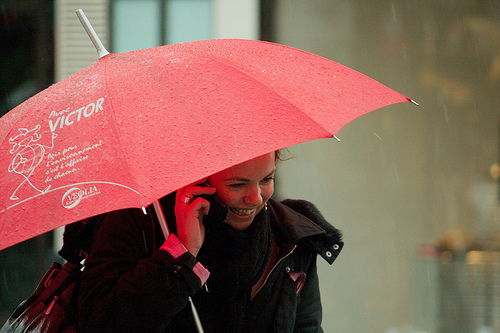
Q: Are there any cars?
A: No, there are no cars.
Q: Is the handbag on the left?
A: Yes, the handbag is on the left of the image.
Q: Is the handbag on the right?
A: No, the handbag is on the left of the image.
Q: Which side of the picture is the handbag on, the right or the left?
A: The handbag is on the left of the image.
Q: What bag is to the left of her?
A: The bag is a handbag.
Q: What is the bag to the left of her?
A: The bag is a handbag.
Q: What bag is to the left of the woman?
A: The bag is a handbag.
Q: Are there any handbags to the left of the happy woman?
A: Yes, there is a handbag to the left of the woman.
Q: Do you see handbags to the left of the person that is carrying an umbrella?
A: Yes, there is a handbag to the left of the woman.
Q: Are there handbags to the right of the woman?
A: No, the handbag is to the left of the woman.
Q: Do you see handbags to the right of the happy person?
A: No, the handbag is to the left of the woman.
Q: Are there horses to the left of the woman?
A: No, there is a handbag to the left of the woman.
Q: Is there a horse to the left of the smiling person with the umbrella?
A: No, there is a handbag to the left of the woman.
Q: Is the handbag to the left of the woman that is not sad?
A: Yes, the handbag is to the left of the woman.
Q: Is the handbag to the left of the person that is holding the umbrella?
A: Yes, the handbag is to the left of the woman.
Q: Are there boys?
A: No, there are no boys.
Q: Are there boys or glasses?
A: No, there are no boys or glasses.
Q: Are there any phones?
A: Yes, there is a phone.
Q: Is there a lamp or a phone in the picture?
A: Yes, there is a phone.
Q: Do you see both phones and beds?
A: No, there is a phone but no beds.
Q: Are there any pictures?
A: No, there are no pictures.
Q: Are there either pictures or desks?
A: No, there are no pictures or desks.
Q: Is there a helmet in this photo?
A: No, there are no helmets.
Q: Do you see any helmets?
A: No, there are no helmets.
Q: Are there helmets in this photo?
A: No, there are no helmets.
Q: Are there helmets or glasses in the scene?
A: No, there are no helmets or glasses.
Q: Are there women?
A: Yes, there is a woman.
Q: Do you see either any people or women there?
A: Yes, there is a woman.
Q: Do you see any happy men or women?
A: Yes, there is a happy woman.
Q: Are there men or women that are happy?
A: Yes, the woman is happy.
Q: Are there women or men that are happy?
A: Yes, the woman is happy.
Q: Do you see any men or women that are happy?
A: Yes, the woman is happy.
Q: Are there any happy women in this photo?
A: Yes, there is a happy woman.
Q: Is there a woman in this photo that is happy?
A: Yes, there is a woman that is happy.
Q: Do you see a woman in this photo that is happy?
A: Yes, there is a woman that is happy.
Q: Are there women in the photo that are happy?
A: Yes, there is a woman that is happy.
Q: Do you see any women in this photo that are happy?
A: Yes, there is a woman that is happy.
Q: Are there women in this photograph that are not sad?
A: Yes, there is a happy woman.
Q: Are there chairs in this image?
A: No, there are no chairs.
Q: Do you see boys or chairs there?
A: No, there are no chairs or boys.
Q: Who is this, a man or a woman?
A: This is a woman.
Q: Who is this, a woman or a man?
A: This is a woman.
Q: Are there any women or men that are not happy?
A: No, there is a woman but she is happy.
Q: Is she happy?
A: Yes, the woman is happy.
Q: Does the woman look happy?
A: Yes, the woman is happy.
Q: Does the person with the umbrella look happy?
A: Yes, the woman is happy.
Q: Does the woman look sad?
A: No, the woman is happy.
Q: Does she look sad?
A: No, the woman is happy.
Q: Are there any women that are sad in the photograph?
A: No, there is a woman but she is happy.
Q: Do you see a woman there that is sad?
A: No, there is a woman but she is happy.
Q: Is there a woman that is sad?
A: No, there is a woman but she is happy.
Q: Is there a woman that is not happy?
A: No, there is a woman but she is happy.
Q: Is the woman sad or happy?
A: The woman is happy.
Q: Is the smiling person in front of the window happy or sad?
A: The woman is happy.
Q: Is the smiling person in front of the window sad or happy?
A: The woman is happy.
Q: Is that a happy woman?
A: Yes, that is a happy woman.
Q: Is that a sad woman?
A: No, that is a happy woman.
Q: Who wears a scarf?
A: The woman wears a scarf.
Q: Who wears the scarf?
A: The woman wears a scarf.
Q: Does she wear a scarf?
A: Yes, the woman wears a scarf.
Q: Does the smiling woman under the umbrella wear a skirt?
A: No, the woman wears a scarf.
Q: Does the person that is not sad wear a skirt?
A: No, the woman wears a scarf.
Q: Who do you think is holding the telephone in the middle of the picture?
A: The woman is holding the phone.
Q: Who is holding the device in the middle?
A: The woman is holding the phone.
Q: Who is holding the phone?
A: The woman is holding the phone.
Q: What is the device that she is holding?
A: The device is a phone.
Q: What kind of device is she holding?
A: The woman is holding the phone.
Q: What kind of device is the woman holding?
A: The woman is holding the phone.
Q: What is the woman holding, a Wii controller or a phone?
A: The woman is holding a phone.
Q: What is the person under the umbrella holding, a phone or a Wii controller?
A: The woman is holding a phone.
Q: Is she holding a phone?
A: Yes, the woman is holding a phone.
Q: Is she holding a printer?
A: No, the woman is holding a phone.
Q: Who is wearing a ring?
A: The woman is wearing a ring.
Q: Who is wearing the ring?
A: The woman is wearing a ring.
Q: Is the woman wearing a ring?
A: Yes, the woman is wearing a ring.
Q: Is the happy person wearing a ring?
A: Yes, the woman is wearing a ring.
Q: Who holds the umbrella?
A: The woman holds the umbrella.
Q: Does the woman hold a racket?
A: No, the woman holds the umbrella.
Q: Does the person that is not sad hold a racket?
A: No, the woman holds the umbrella.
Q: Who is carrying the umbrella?
A: The woman is carrying the umbrella.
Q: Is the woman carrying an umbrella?
A: Yes, the woman is carrying an umbrella.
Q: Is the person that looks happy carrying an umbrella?
A: Yes, the woman is carrying an umbrella.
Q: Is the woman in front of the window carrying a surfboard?
A: No, the woman is carrying an umbrella.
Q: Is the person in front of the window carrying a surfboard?
A: No, the woman is carrying an umbrella.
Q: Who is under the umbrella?
A: The woman is under the umbrella.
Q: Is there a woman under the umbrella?
A: Yes, there is a woman under the umbrella.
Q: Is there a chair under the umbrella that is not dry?
A: No, there is a woman under the umbrella.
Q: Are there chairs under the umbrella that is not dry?
A: No, there is a woman under the umbrella.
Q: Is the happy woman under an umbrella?
A: Yes, the woman is under an umbrella.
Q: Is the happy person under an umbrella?
A: Yes, the woman is under an umbrella.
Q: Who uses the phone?
A: The woman uses the phone.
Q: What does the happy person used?
A: The woman uses a telephone.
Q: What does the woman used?
A: The woman uses a telephone.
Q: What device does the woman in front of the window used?
A: The woman uses a phone.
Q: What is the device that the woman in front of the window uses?
A: The device is a phone.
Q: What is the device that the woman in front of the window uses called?
A: The device is a phone.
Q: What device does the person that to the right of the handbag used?
A: The woman uses a phone.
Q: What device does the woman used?
A: The woman uses a phone.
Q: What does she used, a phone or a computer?
A: The woman uses a phone.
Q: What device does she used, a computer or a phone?
A: The woman uses a phone.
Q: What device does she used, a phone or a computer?
A: The woman uses a phone.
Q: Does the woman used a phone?
A: Yes, the woman uses a phone.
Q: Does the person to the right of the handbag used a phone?
A: Yes, the woman uses a phone.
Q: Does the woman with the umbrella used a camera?
A: No, the woman uses a phone.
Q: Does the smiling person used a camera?
A: No, the woman uses a phone.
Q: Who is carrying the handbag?
A: The woman is carrying the handbag.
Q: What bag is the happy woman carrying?
A: The woman is carrying a handbag.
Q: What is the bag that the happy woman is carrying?
A: The bag is a handbag.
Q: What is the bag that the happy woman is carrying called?
A: The bag is a handbag.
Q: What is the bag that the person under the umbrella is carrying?
A: The bag is a handbag.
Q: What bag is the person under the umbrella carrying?
A: The woman is carrying a handbag.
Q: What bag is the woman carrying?
A: The woman is carrying a handbag.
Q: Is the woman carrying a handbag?
A: Yes, the woman is carrying a handbag.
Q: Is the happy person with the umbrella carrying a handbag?
A: Yes, the woman is carrying a handbag.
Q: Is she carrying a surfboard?
A: No, the woman is carrying a handbag.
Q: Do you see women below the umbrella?
A: Yes, there is a woman below the umbrella.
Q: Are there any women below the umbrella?
A: Yes, there is a woman below the umbrella.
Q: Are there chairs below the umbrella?
A: No, there is a woman below the umbrella.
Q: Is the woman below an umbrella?
A: Yes, the woman is below an umbrella.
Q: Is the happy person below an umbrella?
A: Yes, the woman is below an umbrella.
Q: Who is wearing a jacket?
A: The woman is wearing a jacket.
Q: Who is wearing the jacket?
A: The woman is wearing a jacket.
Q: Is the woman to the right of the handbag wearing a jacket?
A: Yes, the woman is wearing a jacket.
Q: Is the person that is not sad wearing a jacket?
A: Yes, the woman is wearing a jacket.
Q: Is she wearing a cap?
A: No, the woman is wearing a jacket.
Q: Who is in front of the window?
A: The woman is in front of the window.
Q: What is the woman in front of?
A: The woman is in front of the window.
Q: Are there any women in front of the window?
A: Yes, there is a woman in front of the window.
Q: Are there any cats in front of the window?
A: No, there is a woman in front of the window.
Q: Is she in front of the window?
A: Yes, the woman is in front of the window.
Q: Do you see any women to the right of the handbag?
A: Yes, there is a woman to the right of the handbag.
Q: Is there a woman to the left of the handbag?
A: No, the woman is to the right of the handbag.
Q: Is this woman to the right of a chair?
A: No, the woman is to the right of the handbag.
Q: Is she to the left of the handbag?
A: No, the woman is to the right of the handbag.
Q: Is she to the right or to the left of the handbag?
A: The woman is to the right of the handbag.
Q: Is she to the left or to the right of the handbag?
A: The woman is to the right of the handbag.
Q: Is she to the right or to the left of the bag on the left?
A: The woman is to the right of the handbag.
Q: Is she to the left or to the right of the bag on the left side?
A: The woman is to the right of the handbag.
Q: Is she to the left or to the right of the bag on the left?
A: The woman is to the right of the handbag.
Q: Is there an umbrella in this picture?
A: Yes, there is an umbrella.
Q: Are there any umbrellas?
A: Yes, there is an umbrella.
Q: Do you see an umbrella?
A: Yes, there is an umbrella.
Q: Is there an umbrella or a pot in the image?
A: Yes, there is an umbrella.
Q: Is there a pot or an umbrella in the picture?
A: Yes, there is an umbrella.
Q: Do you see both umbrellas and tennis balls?
A: No, there is an umbrella but no tennis balls.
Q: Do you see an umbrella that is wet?
A: Yes, there is a wet umbrella.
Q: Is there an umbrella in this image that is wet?
A: Yes, there is an umbrella that is wet.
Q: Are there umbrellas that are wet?
A: Yes, there is an umbrella that is wet.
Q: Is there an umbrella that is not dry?
A: Yes, there is a wet umbrella.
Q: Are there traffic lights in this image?
A: No, there are no traffic lights.